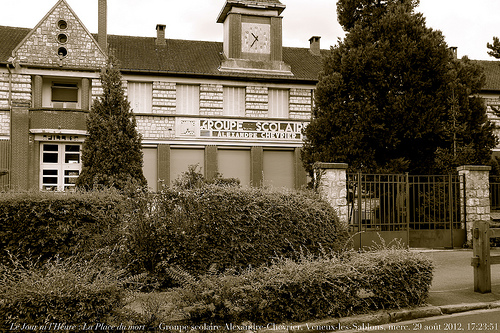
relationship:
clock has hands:
[241, 23, 271, 54] [247, 26, 262, 49]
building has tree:
[0, 1, 498, 230] [303, 1, 495, 213]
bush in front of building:
[0, 186, 145, 271] [0, 1, 498, 230]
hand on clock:
[248, 36, 261, 50] [239, 18, 272, 58]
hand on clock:
[246, 26, 256, 36] [239, 18, 272, 58]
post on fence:
[473, 221, 498, 297] [467, 215, 499, 305]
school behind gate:
[19, 7, 365, 206] [345, 162, 471, 249]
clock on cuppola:
[219, 4, 294, 78] [153, 37, 307, 199]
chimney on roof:
[152, 21, 169, 44] [1, 24, 498, 96]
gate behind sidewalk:
[366, 162, 441, 255] [423, 244, 476, 315]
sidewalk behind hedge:
[403, 232, 498, 310] [6, 247, 433, 326]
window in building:
[41, 142, 58, 163] [0, 0, 325, 199]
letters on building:
[202, 121, 305, 145] [1, 6, 496, 253]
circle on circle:
[57, 47, 74, 61] [55, 33, 73, 48]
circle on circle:
[55, 33, 73, 48] [57, 15, 67, 29]